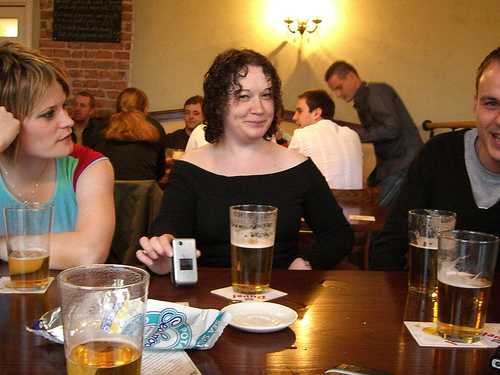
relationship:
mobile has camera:
[170, 237, 199, 284] [177, 239, 183, 247]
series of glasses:
[403, 195, 484, 339] [397, 201, 482, 337]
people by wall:
[323, 59, 421, 206] [2, 0, 499, 140]